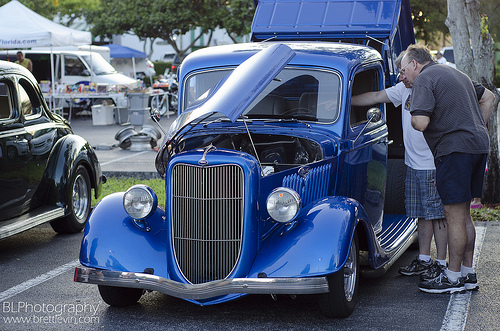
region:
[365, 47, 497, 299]
two men looking inside a car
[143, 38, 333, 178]
side opening front car hood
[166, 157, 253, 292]
large metal car grill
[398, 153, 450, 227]
adult man's plaid shorts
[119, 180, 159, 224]
round headlight on antique car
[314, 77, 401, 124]
man's arm pointing at something inside of a car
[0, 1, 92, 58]
white shad canopy top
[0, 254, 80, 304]
white painted parking spot line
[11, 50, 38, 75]
man in a yellow sleeveless shirt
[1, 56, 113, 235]
antique black car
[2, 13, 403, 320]
Vintage vehicle fan's event.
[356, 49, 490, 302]
Two men shorts sneakers.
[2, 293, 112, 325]
BL Photography Brett Levin.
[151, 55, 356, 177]
Engine hood propped open.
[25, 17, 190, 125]
Market space vendors sell.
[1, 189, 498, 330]
White lines separate parking.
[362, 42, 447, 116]
One man shows another.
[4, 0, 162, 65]
Umbrellas shelter market stands.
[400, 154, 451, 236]
Man plaid shorts tattoed leg.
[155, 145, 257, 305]
Classic grill this vehicle.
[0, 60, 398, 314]
a black vintage car and a blue vintage truck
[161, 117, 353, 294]
front of a blue classic truck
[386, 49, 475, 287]
two men looking inside a blue vintage automobile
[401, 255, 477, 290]
two pairs of men's tennis shoes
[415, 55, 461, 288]
man wearing white socks and solid blue shorts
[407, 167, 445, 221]
man's blue striped shorts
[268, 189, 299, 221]
round headlight on the front of an old automobile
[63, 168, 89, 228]
rear tire of an old black car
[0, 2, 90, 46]
canopy of a white tent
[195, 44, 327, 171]
open hood on an old blue automobile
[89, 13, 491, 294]
men looking at car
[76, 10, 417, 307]
blue car with hood open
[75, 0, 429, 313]
blue car on display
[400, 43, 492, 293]
man wearing gray shirt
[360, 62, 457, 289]
man wearing white shirt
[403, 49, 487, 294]
man wearing blue shorts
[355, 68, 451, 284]
man wearing checkered shorts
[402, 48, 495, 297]
man wearing white socks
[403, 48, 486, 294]
man wearing gray shoes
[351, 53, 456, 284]
man pointing in car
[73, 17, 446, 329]
the car is blue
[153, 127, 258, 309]
the grill is silver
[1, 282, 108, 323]
writing in the bottom left corner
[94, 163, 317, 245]
the headlights are off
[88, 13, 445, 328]
this is an old car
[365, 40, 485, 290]
two men looking at the car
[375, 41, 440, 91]
man is wearing glasses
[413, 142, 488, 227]
the man is wearing shorts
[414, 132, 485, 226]
the shorts are blue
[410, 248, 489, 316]
the man is wearing sneakers